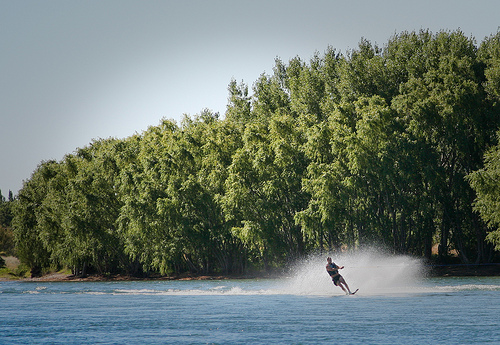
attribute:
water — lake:
[0, 274, 499, 344]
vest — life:
[326, 262, 341, 275]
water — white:
[88, 262, 338, 344]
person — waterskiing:
[322, 255, 352, 295]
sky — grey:
[39, 47, 100, 108]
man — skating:
[326, 254, 359, 299]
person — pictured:
[325, 253, 350, 291]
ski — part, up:
[324, 270, 366, 301]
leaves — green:
[251, 107, 393, 175]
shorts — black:
[319, 259, 346, 298]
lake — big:
[4, 267, 494, 344]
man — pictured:
[312, 230, 359, 321]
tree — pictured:
[383, 35, 475, 267]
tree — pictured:
[348, 96, 428, 271]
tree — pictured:
[216, 159, 282, 279]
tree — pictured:
[17, 158, 82, 273]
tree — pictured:
[112, 135, 197, 280]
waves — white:
[85, 276, 497, 292]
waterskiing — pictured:
[307, 252, 401, 305]